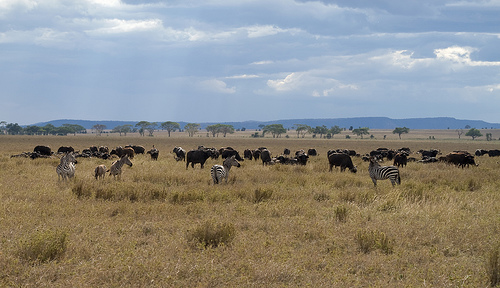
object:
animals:
[210, 157, 239, 184]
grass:
[85, 241, 153, 254]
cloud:
[383, 46, 483, 78]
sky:
[395, 1, 495, 41]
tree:
[158, 120, 181, 136]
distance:
[154, 103, 194, 113]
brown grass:
[132, 135, 210, 144]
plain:
[1, 129, 500, 146]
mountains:
[98, 116, 131, 127]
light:
[151, 49, 362, 112]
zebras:
[56, 151, 78, 180]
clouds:
[89, 11, 324, 94]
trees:
[183, 121, 198, 136]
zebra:
[92, 165, 107, 179]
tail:
[214, 167, 218, 181]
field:
[0, 130, 499, 287]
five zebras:
[56, 151, 401, 190]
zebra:
[367, 158, 402, 189]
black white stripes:
[378, 169, 397, 177]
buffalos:
[108, 147, 135, 160]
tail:
[396, 170, 401, 186]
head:
[224, 154, 241, 168]